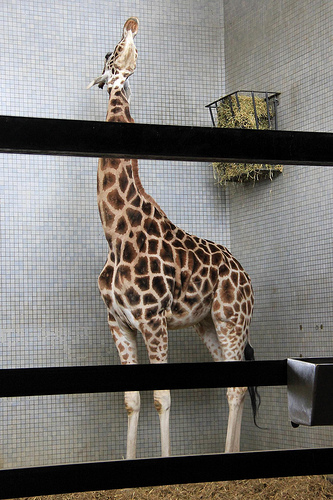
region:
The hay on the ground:
[37, 468, 330, 498]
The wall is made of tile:
[3, 180, 92, 340]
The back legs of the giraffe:
[197, 324, 251, 461]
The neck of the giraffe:
[94, 91, 141, 223]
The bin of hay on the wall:
[197, 82, 285, 184]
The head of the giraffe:
[85, 10, 144, 96]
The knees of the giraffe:
[114, 392, 168, 418]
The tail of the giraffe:
[240, 325, 271, 433]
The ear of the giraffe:
[85, 72, 107, 91]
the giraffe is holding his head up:
[86, 14, 142, 94]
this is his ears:
[83, 71, 103, 95]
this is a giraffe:
[84, 15, 267, 479]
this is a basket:
[206, 87, 281, 182]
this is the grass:
[6, 475, 332, 499]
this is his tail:
[243, 334, 273, 432]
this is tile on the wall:
[2, 0, 330, 480]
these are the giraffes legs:
[103, 314, 260, 460]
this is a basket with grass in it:
[204, 89, 281, 184]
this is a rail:
[0, 117, 328, 165]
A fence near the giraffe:
[0, 357, 331, 499]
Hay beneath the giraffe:
[9, 475, 331, 499]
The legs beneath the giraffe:
[112, 326, 170, 459]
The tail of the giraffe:
[244, 334, 267, 431]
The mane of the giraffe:
[132, 117, 163, 211]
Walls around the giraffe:
[0, 0, 331, 468]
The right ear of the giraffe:
[90, 74, 105, 88]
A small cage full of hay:
[209, 91, 281, 184]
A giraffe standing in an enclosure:
[90, 18, 266, 459]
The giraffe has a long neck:
[97, 97, 142, 196]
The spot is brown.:
[115, 165, 128, 196]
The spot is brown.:
[150, 336, 161, 346]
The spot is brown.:
[142, 325, 152, 340]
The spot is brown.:
[116, 339, 126, 352]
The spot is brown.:
[119, 351, 132, 360]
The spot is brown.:
[218, 323, 228, 336]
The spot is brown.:
[212, 310, 225, 323]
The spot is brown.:
[222, 302, 236, 320]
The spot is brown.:
[216, 277, 236, 307]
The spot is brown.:
[140, 290, 160, 308]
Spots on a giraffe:
[124, 257, 163, 296]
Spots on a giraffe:
[129, 273, 175, 320]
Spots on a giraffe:
[106, 266, 164, 323]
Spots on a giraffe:
[138, 261, 196, 316]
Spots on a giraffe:
[105, 252, 191, 311]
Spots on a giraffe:
[112, 250, 186, 314]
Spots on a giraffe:
[149, 260, 204, 307]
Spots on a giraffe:
[105, 267, 181, 325]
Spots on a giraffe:
[145, 263, 220, 314]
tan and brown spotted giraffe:
[83, 13, 307, 420]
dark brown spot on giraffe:
[129, 253, 150, 279]